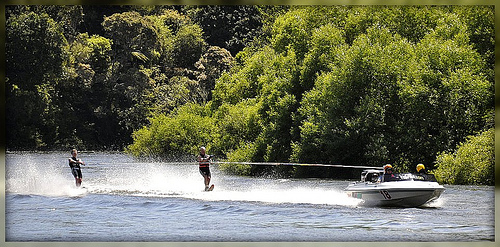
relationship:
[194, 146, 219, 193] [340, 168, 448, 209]
people holding boat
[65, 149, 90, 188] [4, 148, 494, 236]
guy in water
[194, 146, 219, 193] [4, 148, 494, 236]
people in water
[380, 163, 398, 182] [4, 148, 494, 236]
people in water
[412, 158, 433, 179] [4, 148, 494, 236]
person in water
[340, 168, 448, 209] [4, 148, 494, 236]
boat in water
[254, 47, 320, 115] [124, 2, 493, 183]
leaves on tree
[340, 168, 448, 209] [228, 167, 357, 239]
boat in water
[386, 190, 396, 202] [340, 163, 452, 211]
number in boat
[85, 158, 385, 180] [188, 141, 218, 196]
rope pulling skiers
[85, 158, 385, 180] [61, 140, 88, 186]
rope pulling skiers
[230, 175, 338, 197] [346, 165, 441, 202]
wake behind boat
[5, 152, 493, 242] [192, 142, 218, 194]
wake splashing behind skier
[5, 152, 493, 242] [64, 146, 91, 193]
wake splashing behind skier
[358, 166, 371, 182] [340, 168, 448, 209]
motor on back of boat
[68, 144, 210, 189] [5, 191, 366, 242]
people out on water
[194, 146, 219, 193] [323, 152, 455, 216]
people are pulled by boat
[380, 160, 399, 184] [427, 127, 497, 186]
people close to tree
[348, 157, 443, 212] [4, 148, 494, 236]
boat in water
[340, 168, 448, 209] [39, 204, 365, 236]
boat in water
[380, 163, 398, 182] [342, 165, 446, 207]
people on boat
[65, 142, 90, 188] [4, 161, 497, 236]
guy on water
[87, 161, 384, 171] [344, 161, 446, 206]
rope from boat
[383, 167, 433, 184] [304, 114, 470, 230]
windshield on boat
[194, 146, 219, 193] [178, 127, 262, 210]
people riding skis